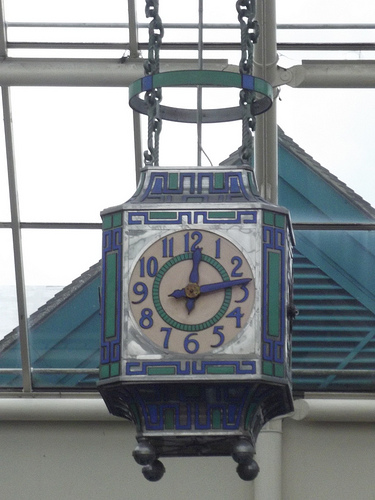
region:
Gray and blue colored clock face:
[130, 228, 256, 351]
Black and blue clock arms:
[166, 245, 253, 316]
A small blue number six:
[181, 331, 199, 355]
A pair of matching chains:
[141, 0, 261, 162]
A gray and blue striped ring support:
[125, 69, 275, 123]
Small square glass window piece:
[18, 228, 104, 363]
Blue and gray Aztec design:
[120, 358, 257, 373]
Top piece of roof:
[277, 123, 373, 222]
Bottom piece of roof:
[29, 256, 102, 369]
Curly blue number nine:
[131, 282, 149, 305]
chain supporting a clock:
[225, 3, 272, 131]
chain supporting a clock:
[143, 5, 170, 167]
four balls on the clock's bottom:
[125, 441, 274, 482]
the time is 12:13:
[112, 207, 271, 365]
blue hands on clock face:
[163, 243, 254, 328]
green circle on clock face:
[148, 249, 229, 334]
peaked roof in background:
[0, 116, 368, 353]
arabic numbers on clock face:
[127, 228, 254, 360]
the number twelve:
[178, 229, 206, 252]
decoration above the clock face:
[120, 210, 261, 227]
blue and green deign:
[129, 376, 261, 430]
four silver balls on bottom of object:
[114, 442, 263, 497]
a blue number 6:
[167, 328, 205, 374]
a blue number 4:
[227, 304, 246, 334]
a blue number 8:
[126, 306, 155, 341]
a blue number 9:
[122, 273, 155, 315]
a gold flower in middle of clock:
[169, 277, 202, 313]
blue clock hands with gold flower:
[135, 241, 232, 358]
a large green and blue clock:
[131, 208, 280, 449]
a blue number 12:
[178, 227, 209, 262]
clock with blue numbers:
[130, 217, 255, 333]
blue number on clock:
[176, 319, 211, 362]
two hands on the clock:
[164, 255, 229, 315]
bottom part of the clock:
[128, 396, 272, 457]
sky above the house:
[44, 110, 93, 156]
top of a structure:
[256, 121, 341, 181]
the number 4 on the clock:
[220, 301, 250, 333]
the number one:
[203, 234, 234, 267]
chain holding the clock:
[136, 103, 184, 153]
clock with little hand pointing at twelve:
[140, 222, 262, 335]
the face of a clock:
[127, 227, 257, 356]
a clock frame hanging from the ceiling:
[96, 162, 303, 484]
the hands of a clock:
[166, 243, 254, 319]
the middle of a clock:
[183, 280, 202, 300]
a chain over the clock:
[135, 0, 162, 165]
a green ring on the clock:
[151, 250, 233, 334]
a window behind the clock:
[7, 83, 139, 226]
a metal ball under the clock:
[125, 435, 163, 469]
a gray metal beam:
[282, 59, 374, 91]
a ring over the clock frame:
[125, 68, 276, 129]